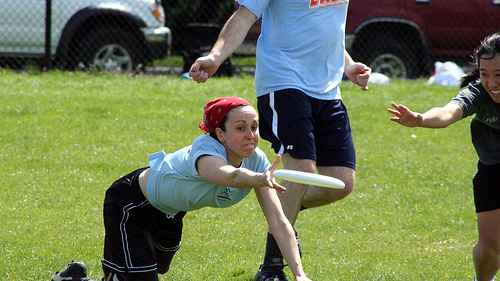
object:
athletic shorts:
[256, 89, 356, 169]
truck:
[0, 0, 171, 74]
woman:
[385, 34, 498, 281]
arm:
[386, 82, 478, 129]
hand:
[386, 101, 424, 128]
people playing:
[0, 0, 500, 280]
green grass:
[26, 110, 117, 148]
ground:
[0, 37, 500, 281]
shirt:
[238, 0, 347, 101]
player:
[187, 0, 369, 281]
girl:
[52, 96, 312, 281]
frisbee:
[271, 168, 346, 189]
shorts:
[97, 165, 185, 278]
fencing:
[0, 0, 499, 85]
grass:
[0, 69, 498, 280]